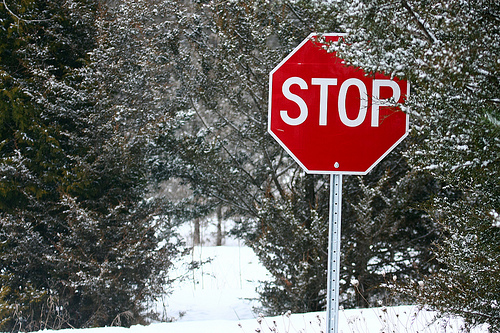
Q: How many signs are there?
A: 1.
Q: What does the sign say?
A: Stop.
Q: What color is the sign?
A: Red.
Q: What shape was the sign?
A: Octagon.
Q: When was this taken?
A: Winter.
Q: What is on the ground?
A: Snow.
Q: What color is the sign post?
A: Silver.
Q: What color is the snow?
A: White.